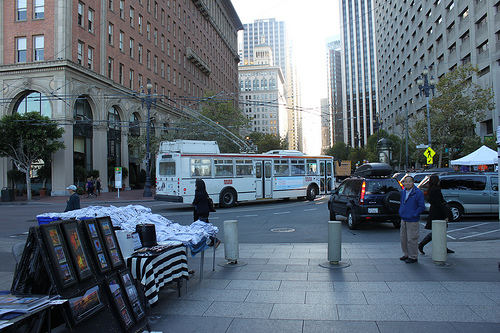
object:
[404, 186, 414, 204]
shirt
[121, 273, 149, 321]
artwork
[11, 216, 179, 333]
display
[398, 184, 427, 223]
jacket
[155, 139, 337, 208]
bus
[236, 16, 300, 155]
building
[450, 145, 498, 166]
canopy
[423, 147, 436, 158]
walk sign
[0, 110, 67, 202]
tree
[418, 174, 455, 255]
lady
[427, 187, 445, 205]
black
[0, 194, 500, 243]
street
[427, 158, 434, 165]
sign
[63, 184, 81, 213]
man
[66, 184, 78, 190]
cap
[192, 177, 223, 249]
woman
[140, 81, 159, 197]
lamp post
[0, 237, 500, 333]
sidewalk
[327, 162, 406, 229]
suv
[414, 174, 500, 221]
minivan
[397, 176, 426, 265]
pedestrian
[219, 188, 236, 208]
tire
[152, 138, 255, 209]
rear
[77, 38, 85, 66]
window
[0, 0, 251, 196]
building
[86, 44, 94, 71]
window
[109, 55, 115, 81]
window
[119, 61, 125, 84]
window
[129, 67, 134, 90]
window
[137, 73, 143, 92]
window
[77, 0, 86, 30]
window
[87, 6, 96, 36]
window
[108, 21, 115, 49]
window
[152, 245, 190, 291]
part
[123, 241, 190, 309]
cloth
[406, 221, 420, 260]
part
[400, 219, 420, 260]
trouser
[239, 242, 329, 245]
edge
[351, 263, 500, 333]
part